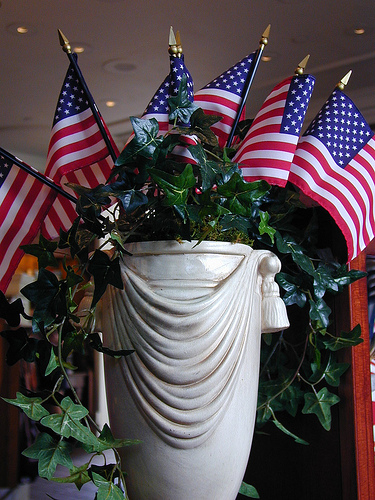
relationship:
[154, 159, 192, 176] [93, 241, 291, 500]
plant in vase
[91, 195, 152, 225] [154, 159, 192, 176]
leaf of plant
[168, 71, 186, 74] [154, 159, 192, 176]
flag on plant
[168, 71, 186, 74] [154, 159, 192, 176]
flag in plant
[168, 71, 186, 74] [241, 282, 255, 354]
flag in vase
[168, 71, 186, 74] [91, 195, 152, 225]
flag behind leaf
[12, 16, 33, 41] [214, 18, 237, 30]
lights on ceiling